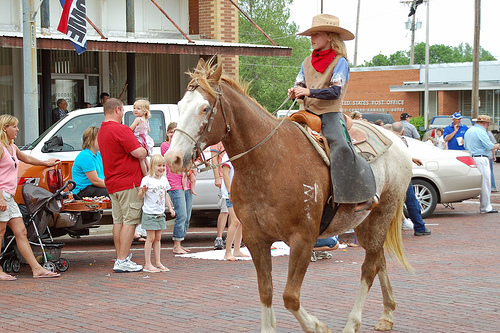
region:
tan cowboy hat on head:
[286, 10, 365, 34]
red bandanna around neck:
[305, 48, 339, 71]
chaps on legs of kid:
[311, 113, 379, 210]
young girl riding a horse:
[168, 11, 408, 303]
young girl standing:
[113, 155, 173, 270]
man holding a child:
[74, 93, 150, 286]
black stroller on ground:
[20, 169, 84, 269]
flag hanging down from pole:
[38, 0, 97, 48]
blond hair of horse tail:
[388, 203, 419, 278]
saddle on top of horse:
[275, 112, 394, 171]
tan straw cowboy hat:
[303, 15, 354, 40]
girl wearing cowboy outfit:
[288, 17, 374, 208]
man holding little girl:
[104, 98, 149, 270]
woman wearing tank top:
[1, 112, 49, 287]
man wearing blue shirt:
[467, 114, 498, 216]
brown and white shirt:
[173, 63, 410, 331]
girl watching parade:
[141, 154, 174, 274]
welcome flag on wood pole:
[58, 3, 112, 50]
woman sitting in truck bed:
[74, 126, 106, 208]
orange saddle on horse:
[286, 109, 352, 129]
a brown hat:
[298, 13, 360, 43]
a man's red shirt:
[97, 118, 146, 195]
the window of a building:
[134, 55, 177, 101]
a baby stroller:
[0, 176, 76, 276]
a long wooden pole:
[461, 0, 482, 116]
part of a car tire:
[410, 178, 435, 214]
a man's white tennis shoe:
[110, 250, 141, 270]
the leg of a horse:
[358, 225, 393, 321]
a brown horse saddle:
[285, 108, 321, 128]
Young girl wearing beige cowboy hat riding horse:
[266, 14, 383, 211]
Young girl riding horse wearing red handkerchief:
[279, 15, 386, 217]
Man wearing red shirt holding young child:
[95, 95, 145, 273]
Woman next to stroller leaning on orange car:
[0, 116, 66, 280]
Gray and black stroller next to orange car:
[0, 181, 77, 274]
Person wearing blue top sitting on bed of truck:
[71, 121, 108, 196]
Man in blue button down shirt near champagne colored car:
[460, 113, 498, 218]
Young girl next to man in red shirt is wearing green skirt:
[137, 155, 179, 275]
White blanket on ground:
[170, 239, 292, 256]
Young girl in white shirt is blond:
[137, 155, 180, 275]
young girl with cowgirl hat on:
[160, 5, 428, 320]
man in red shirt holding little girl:
[94, 84, 174, 284]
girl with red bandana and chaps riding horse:
[158, 9, 425, 319]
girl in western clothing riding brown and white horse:
[151, 5, 441, 322]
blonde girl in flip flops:
[121, 145, 186, 284]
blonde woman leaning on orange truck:
[1, 106, 71, 299]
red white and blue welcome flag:
[56, 0, 128, 76]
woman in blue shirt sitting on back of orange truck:
[65, 98, 125, 220]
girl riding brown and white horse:
[159, 10, 441, 325]